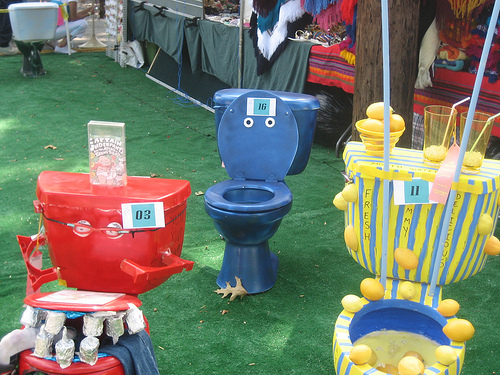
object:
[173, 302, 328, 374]
floor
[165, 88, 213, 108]
part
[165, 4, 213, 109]
line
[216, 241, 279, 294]
p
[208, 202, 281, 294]
base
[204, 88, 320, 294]
toilet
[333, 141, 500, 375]
toilet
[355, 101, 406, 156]
lemons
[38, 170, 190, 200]
hard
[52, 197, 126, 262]
surface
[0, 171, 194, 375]
part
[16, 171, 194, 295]
tank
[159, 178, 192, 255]
side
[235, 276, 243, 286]
edge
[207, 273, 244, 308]
leaf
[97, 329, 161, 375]
part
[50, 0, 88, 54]
part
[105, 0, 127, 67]
board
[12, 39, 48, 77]
edge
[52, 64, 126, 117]
field